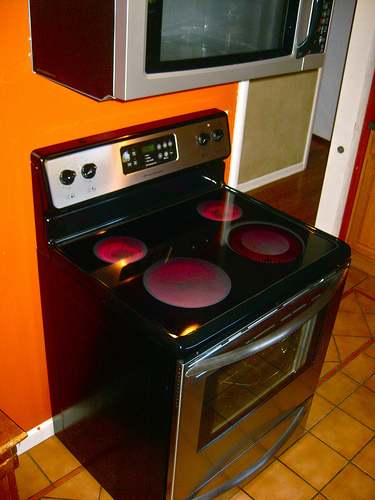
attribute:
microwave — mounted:
[19, 1, 344, 106]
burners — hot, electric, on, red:
[72, 190, 323, 319]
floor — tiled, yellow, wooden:
[0, 251, 373, 499]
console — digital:
[106, 131, 200, 173]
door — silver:
[166, 274, 351, 499]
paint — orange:
[32, 424, 44, 437]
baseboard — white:
[11, 410, 56, 454]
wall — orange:
[2, 3, 51, 450]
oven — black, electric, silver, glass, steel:
[15, 102, 366, 499]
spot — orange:
[32, 424, 44, 431]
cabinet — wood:
[345, 125, 371, 274]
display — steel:
[30, 115, 255, 192]